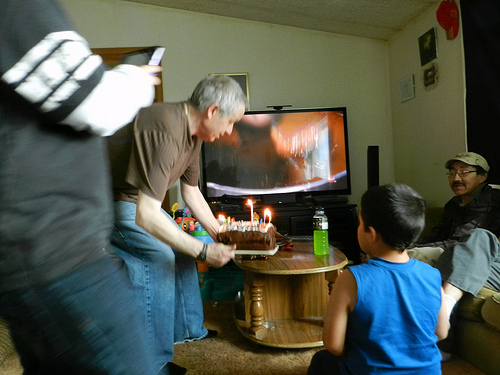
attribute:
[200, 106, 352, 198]
screen — flat, on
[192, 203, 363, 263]
table — black, wooden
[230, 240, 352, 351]
table — wooden, rounded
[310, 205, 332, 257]
bottle — clear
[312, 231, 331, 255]
juice — green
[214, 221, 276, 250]
cake — chocolate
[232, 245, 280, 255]
platter — white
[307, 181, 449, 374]
kid — sitting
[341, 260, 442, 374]
shirt — blue, sleeveles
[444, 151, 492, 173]
hat — light colored, light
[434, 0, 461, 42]
hat — red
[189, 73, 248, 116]
hair — grey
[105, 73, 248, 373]
man — old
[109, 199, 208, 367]
jeans — blue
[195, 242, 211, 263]
watch — black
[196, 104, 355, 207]
tv — large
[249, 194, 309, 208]
stand — small, black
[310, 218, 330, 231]
labeling — black